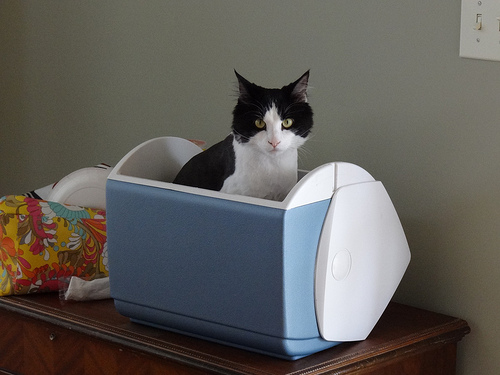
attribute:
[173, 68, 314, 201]
cat — sitting, black, white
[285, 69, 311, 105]
ear — black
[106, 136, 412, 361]
cooler — blue, white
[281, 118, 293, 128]
eye — open, green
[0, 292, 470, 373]
table — wooden, dark brown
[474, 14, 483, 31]
light switch — white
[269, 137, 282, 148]
nose — pink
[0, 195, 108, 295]
bag — colorful, multi colored, bright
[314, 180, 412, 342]
cover — white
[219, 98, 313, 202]
hair — white